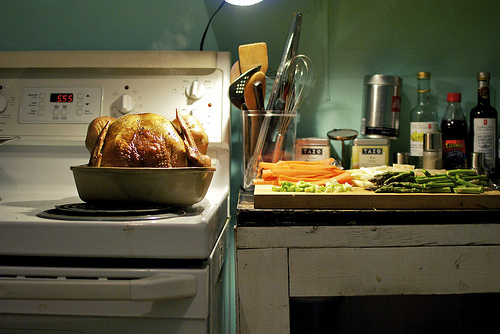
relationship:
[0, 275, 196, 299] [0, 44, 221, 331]
handle on oven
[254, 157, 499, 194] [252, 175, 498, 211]
veggies on board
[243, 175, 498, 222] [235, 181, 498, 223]
board on counter top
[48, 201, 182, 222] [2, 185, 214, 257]
grill on stove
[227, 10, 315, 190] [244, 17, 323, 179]
kitchen utensils in bucket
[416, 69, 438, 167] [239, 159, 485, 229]
bottle on counter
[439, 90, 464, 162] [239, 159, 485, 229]
bottle on counter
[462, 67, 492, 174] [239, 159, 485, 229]
bottle on counter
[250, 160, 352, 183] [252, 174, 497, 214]
carrots on board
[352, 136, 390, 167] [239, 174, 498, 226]
tea tin on counter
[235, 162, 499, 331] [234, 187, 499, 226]
table has top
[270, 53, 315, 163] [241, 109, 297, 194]
kitchen utensil in clear container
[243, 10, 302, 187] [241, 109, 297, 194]
kitchen utensil in clear container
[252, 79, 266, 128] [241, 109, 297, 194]
kitchen utensil in clear container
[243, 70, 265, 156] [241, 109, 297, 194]
kitchen utensil in clear container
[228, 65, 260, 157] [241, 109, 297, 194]
kitchen utensil in clear container